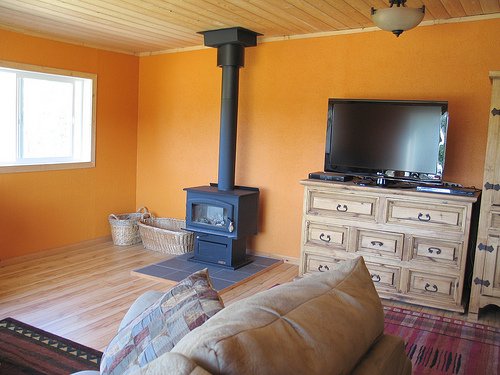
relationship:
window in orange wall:
[2, 60, 99, 176] [96, 55, 217, 181]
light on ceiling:
[365, 3, 430, 41] [0, 3, 370, 26]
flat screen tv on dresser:
[325, 98, 446, 189] [303, 180, 479, 314]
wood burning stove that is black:
[183, 189, 261, 232] [184, 26, 260, 267]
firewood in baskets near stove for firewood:
[107, 208, 195, 255] [184, 26, 260, 267]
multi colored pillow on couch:
[96, 267, 223, 373] [97, 257, 410, 372]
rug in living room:
[0, 313, 110, 373] [2, 0, 497, 374]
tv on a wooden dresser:
[325, 98, 446, 189] [303, 180, 479, 314]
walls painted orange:
[0, 54, 498, 252] [2, 33, 499, 101]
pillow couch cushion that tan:
[97, 257, 410, 372] [229, 252, 412, 374]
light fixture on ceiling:
[365, 3, 430, 41] [0, 3, 370, 26]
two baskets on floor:
[107, 208, 195, 255] [0, 245, 155, 350]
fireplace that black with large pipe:
[184, 26, 260, 267] [200, 30, 261, 192]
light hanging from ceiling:
[365, 3, 430, 41] [0, 3, 370, 26]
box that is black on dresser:
[309, 172, 355, 183] [303, 180, 479, 314]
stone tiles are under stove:
[131, 251, 283, 292] [173, 183, 261, 271]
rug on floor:
[382, 304, 484, 370] [2, 244, 482, 373]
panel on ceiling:
[297, 3, 346, 56] [3, 1, 481, 44]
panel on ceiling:
[151, 4, 230, 38] [3, 1, 481, 44]